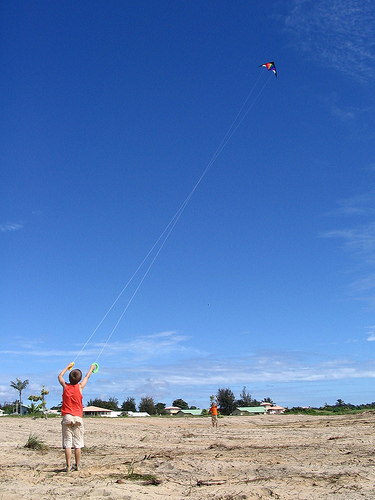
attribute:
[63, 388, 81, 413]
shirt — orange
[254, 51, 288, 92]
sky — blue, clera, cloudy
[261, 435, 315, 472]
sand — tan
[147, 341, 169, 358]
clouds — white